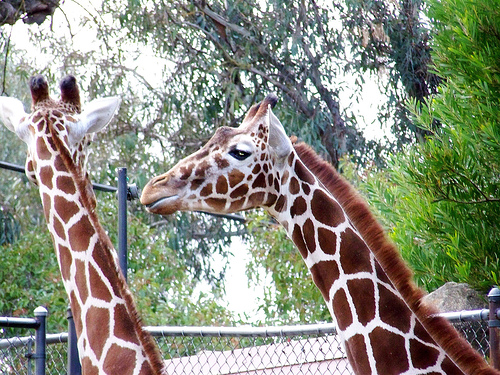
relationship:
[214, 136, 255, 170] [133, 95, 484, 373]
eye of giraffe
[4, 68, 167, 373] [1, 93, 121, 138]
giraffe with ears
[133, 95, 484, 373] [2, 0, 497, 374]
giraffe in zoo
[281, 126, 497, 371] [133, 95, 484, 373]
mane on giraffe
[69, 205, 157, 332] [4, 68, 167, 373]
mane on giraffe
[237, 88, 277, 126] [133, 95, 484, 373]
horns on giraffe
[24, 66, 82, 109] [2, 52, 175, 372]
horns on giraffe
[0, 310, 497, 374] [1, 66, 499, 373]
fence by giraffes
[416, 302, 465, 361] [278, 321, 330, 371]
rock outside fence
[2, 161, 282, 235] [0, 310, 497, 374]
bar outside fence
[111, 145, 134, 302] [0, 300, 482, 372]
pole outside fence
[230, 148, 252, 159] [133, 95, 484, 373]
eye part of giraffe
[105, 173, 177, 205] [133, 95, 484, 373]
nose part of giraffe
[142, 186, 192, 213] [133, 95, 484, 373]
mouth part of giraffe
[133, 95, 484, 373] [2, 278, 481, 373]
giraffe near fence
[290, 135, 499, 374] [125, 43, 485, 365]
mane on giraffe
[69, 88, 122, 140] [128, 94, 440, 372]
ear on giraffe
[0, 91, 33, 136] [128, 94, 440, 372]
ear on giraffe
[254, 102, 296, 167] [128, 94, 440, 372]
ear on giraffe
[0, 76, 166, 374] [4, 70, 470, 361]
giraffe in compound